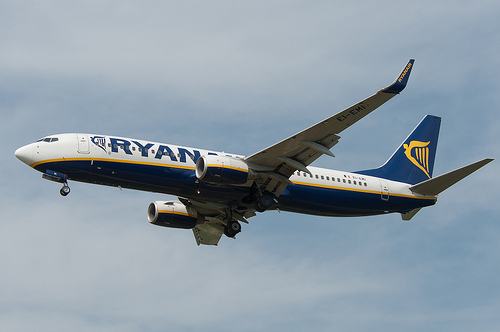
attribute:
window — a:
[306, 173, 316, 176]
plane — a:
[15, 112, 457, 219]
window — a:
[104, 141, 111, 146]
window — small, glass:
[346, 175, 351, 187]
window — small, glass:
[298, 167, 308, 179]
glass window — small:
[346, 176, 353, 188]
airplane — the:
[20, 97, 450, 223]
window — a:
[149, 148, 158, 158]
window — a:
[131, 145, 136, 151]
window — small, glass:
[363, 180, 368, 185]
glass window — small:
[298, 171, 308, 181]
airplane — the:
[22, 85, 447, 267]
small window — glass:
[324, 174, 331, 182]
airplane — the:
[10, 57, 494, 250]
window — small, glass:
[336, 175, 341, 182]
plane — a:
[34, 58, 484, 302]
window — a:
[311, 157, 388, 204]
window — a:
[130, 145, 137, 152]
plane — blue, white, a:
[11, 54, 495, 248]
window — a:
[360, 179, 370, 189]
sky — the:
[2, 2, 499, 330]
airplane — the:
[1, 34, 498, 260]